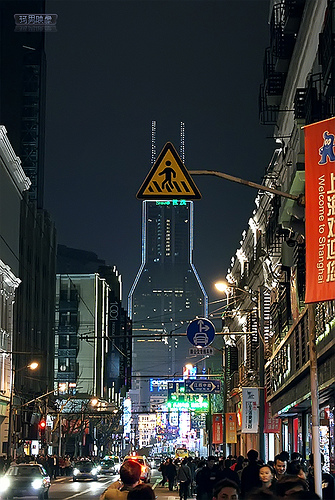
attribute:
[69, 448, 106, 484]
car — small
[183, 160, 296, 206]
pole — metal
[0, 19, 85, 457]
building — black , tall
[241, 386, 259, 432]
banner — white and black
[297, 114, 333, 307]
banner — red and white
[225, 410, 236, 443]
banner — orange, yellow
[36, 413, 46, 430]
traffic light — red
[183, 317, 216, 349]
sign — blue and white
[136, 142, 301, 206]
pole — metal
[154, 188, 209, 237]
lights — white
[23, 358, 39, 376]
light — overhead, street light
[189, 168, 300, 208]
pole — metal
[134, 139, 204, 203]
sign — yellow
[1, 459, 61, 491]
car — small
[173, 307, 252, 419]
sign — blue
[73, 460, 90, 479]
car — small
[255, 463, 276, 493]
person — walking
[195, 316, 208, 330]
arrows — white